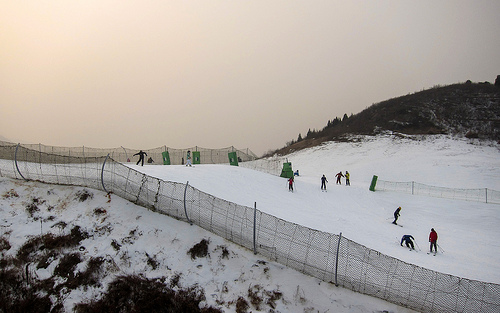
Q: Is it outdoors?
A: Yes, it is outdoors.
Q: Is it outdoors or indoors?
A: It is outdoors.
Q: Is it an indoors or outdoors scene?
A: It is outdoors.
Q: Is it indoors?
A: No, it is outdoors.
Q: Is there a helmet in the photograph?
A: No, there are no helmets.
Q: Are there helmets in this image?
A: No, there are no helmets.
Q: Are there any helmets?
A: No, there are no helmets.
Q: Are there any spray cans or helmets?
A: No, there are no helmets or spray cans.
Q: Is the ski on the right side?
A: Yes, the ski is on the right of the image.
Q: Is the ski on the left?
A: No, the ski is on the right of the image.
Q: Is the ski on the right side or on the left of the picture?
A: The ski is on the right of the image.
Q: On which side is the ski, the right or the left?
A: The ski is on the right of the image.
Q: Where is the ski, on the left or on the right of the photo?
A: The ski is on the right of the image.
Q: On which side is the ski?
A: The ski is on the right of the image.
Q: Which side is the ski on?
A: The ski is on the right of the image.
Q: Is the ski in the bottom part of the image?
A: Yes, the ski is in the bottom of the image.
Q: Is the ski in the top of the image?
A: No, the ski is in the bottom of the image.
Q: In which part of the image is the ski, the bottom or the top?
A: The ski is in the bottom of the image.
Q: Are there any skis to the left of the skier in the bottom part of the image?
A: Yes, there is a ski to the left of the skier.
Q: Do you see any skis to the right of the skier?
A: No, the ski is to the left of the skier.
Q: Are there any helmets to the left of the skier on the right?
A: No, there is a ski to the left of the skier.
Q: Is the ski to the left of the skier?
A: Yes, the ski is to the left of the skier.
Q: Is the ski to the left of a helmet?
A: No, the ski is to the left of the skier.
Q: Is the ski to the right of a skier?
A: No, the ski is to the left of a skier.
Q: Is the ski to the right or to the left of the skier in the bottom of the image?
A: The ski is to the left of the skier.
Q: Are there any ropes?
A: No, there are no ropes.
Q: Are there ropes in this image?
A: No, there are no ropes.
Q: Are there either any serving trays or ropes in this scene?
A: No, there are no ropes or serving trays.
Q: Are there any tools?
A: No, there are no tools.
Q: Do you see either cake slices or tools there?
A: No, there are no tools or cake slices.